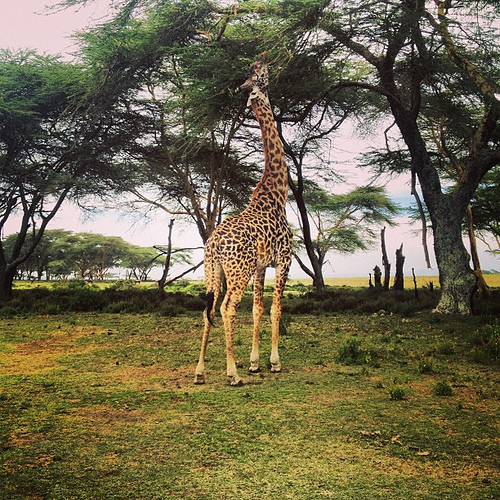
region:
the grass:
[261, 416, 327, 451]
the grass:
[237, 396, 317, 490]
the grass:
[274, 385, 329, 475]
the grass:
[262, 445, 299, 492]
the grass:
[289, 488, 327, 497]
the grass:
[285, 417, 316, 450]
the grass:
[300, 451, 367, 496]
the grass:
[288, 449, 316, 494]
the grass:
[269, 431, 311, 492]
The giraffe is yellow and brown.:
[163, 65, 336, 400]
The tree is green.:
[0, 0, 350, 120]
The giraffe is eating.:
[233, 40, 301, 116]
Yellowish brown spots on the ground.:
[18, 347, 184, 454]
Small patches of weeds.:
[341, 332, 464, 400]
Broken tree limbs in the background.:
[358, 226, 418, 306]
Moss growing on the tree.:
[431, 235, 473, 319]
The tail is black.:
[198, 281, 223, 330]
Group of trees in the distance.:
[7, 230, 160, 285]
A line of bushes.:
[17, 280, 198, 320]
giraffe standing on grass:
[188, 51, 298, 388]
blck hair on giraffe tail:
[205, 290, 223, 325]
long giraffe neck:
[254, 100, 289, 204]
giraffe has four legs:
[219, 289, 248, 382]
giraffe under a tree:
[81, 2, 498, 317]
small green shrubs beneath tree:
[334, 336, 375, 369]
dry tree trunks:
[394, 244, 402, 285]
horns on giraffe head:
[233, 72, 263, 94]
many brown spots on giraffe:
[270, 130, 280, 138]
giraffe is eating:
[186, 50, 298, 386]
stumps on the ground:
[369, 224, 413, 296]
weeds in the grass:
[328, 310, 498, 415]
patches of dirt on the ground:
[85, 365, 184, 463]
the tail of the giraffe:
[197, 247, 222, 331]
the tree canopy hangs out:
[299, 177, 399, 257]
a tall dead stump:
[157, 218, 174, 288]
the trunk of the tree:
[422, 183, 487, 325]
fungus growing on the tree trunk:
[434, 218, 479, 304]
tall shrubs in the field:
[52, 270, 187, 308]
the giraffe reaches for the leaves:
[234, 45, 284, 112]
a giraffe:
[160, 125, 290, 435]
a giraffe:
[207, 95, 372, 423]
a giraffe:
[142, 35, 327, 336]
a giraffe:
[224, 42, 298, 487]